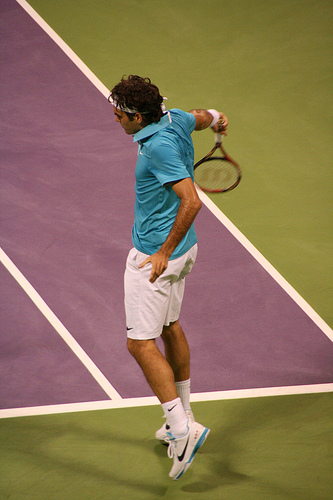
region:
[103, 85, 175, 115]
White sweatband on a tennis players head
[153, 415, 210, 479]
White Nike tennis shoes with a black Nike check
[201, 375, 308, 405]
Multiple colors and lines on a tennis court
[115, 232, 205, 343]
White Nike tennis shorts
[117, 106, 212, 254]
Aqua colored short sleeved shirt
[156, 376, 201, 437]
White Nike socks with black Nike check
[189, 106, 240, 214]
Tennis racket in right hand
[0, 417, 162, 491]
Shadow of tennis player on the ground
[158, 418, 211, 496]
White Nike tennis shoes with aqua colored trim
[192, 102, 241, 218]
Wilson tennis racket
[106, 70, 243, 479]
a male tennis player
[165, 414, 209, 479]
a blue and white tennis shoe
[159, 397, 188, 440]
a white men's sock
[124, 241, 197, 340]
a pair of men's white shorts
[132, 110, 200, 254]
a man's blue polo shirt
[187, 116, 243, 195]
a red and black tennis racket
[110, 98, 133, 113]
a white head band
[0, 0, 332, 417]
a purple lined tennis court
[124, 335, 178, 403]
a man's bare left leg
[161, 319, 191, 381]
a man's bare right leg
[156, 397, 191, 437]
White sock with black checkmark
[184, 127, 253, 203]
Red and black tennis racket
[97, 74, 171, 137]
Man's head with dark curly hair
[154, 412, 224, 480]
White and blue shoe with black checkmark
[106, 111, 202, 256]
Bright blue polo shirt with white designs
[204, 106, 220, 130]
White sweatband on the man's arm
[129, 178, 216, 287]
Man's tanned left arm in motion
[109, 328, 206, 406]
Middle of the man's tanned legs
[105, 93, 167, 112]
White sweatband around the man's head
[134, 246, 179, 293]
Man's open hand by his side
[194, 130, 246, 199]
black and orange tennis racquet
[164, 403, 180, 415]
company logo on side of socks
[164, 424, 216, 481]
white and blue tennis shoe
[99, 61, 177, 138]
tennis player in white headband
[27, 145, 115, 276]
purple turf on tennis court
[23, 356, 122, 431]
white lines painted on tennis court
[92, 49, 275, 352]
tennis player swinging racquet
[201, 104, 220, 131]
white wristband on tennis player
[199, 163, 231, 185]
logo on tennis racquet netting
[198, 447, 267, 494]
shadow of tennis player on ground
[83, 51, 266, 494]
This is a person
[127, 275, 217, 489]
These are legs of a person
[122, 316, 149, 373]
This is a knee of a person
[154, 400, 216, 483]
These are sport shoes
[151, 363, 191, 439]
This is a pair of white socks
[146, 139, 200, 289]
This is a hand of a person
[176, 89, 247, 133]
This is a hand of a person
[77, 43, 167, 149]
Head of a person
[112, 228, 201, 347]
Pair of white shots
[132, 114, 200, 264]
This is a blue tshirt